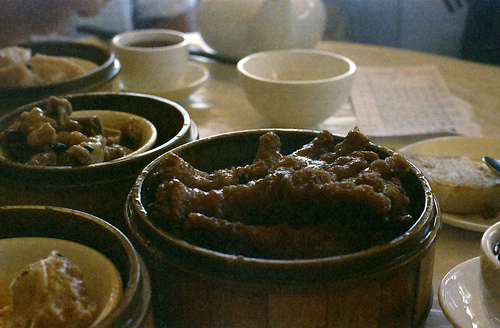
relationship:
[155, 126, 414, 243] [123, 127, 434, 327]
food in bowl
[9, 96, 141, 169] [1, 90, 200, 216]
food in bowl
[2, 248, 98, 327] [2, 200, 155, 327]
food in bowl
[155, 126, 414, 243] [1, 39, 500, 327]
food on table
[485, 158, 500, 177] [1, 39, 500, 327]
spoon on table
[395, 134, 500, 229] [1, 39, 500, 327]
plate on table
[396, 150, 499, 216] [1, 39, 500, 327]
cake ont table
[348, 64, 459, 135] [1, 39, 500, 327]
napkin on table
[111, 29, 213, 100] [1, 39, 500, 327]
coffee ont table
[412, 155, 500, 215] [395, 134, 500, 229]
cake on plate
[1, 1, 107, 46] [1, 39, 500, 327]
hand over table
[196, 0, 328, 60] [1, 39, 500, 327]
pitcher on table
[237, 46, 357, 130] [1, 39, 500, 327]
bowl of table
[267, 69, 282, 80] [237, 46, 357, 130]
light reflection on bowl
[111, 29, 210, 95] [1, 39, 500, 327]
coffee on table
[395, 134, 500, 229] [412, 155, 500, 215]
plate with cake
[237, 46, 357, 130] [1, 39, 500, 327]
bowl on table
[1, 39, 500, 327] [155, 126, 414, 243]
table with food